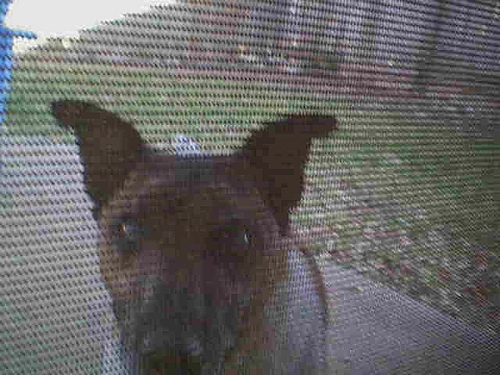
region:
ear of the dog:
[266, 115, 332, 143]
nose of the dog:
[137, 313, 201, 369]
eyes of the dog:
[114, 218, 253, 260]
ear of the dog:
[65, 114, 126, 194]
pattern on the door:
[406, 174, 453, 221]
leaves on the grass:
[414, 238, 477, 294]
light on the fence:
[36, 17, 76, 30]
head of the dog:
[62, 99, 294, 361]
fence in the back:
[322, 25, 387, 50]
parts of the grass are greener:
[388, 142, 420, 164]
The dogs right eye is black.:
[108, 211, 143, 248]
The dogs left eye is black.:
[219, 223, 255, 262]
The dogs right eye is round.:
[113, 210, 144, 249]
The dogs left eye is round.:
[215, 223, 260, 263]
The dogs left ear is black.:
[245, 106, 337, 225]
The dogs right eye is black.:
[48, 93, 153, 207]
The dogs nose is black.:
[135, 319, 207, 374]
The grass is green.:
[385, 113, 463, 168]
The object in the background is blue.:
[1, 3, 27, 119]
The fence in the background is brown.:
[353, 9, 479, 69]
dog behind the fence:
[41, 90, 341, 368]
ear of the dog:
[233, 93, 340, 190]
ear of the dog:
[49, 97, 159, 180]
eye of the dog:
[207, 220, 251, 260]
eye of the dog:
[108, 213, 164, 263]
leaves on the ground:
[426, 271, 476, 299]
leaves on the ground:
[380, 231, 425, 271]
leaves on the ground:
[341, 215, 366, 243]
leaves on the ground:
[404, 202, 448, 224]